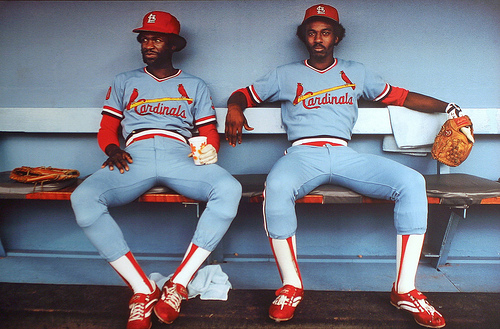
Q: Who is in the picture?
A: Two men.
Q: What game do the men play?
A: Baseball.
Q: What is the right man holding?
A: A mitt.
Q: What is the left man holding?
A: A coffee cup.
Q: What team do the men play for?
A: Cardinals.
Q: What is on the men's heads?
A: Hats.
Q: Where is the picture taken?
A: Dugout.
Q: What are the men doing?
A: Sitting.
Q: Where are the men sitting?
A: A bench.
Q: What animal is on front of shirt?
A: Bird.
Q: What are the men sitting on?
A: Bench.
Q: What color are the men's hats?
A: Red.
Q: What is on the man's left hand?
A: Glove.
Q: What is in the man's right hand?
A: Cup.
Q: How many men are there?
A: Two.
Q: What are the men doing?
A: Sitting on bench.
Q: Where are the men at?
A: Baseball game.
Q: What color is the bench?
A: Brown.